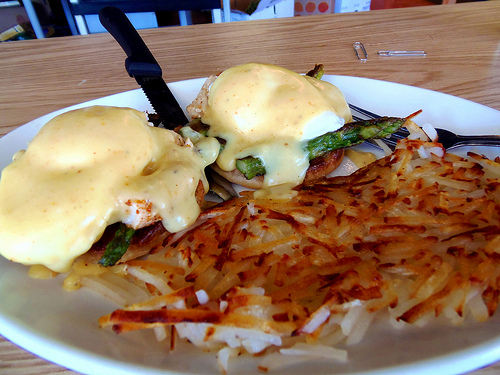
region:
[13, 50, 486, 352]
A serving of eggs and hash browns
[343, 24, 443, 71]
Two paperclips on the table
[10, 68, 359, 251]
A serving of eggs Benedict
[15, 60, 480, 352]
A large breakfast serving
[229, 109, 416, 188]
A piece of asparagus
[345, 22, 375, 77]
A paperclip on a table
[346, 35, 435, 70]
Two paperclips next to each other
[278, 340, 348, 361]
white colored hash brown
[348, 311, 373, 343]
white colored hash brown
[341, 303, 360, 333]
white colored hash brown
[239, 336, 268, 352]
white colored hash brown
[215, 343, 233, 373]
white colored hash brown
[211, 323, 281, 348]
white colored hash brown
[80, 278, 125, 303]
white colored hash brown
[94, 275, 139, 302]
white colored hash brown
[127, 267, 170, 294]
white colored hash brown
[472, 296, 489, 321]
white colored hash brown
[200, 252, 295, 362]
section of a food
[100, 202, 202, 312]
section of a food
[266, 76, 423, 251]
section of a food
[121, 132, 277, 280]
section of a food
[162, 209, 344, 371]
section of a food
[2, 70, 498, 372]
white plate with food on it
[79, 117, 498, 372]
hashbrowns on a plate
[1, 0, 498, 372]
wooden table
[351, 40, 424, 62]
two paperclips on a wooden table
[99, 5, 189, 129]
knife with a black handle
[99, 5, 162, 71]
black knife handle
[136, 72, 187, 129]
serrated blade of knife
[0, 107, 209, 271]
orange sauce on food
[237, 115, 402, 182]
green asperagus with sauce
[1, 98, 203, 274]
poached egg with hollandaise sauce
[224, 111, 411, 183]
spear of green asparagus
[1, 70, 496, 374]
white ceramic breakfast plate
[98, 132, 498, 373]
golden brown potato hashbrowns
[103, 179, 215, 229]
sprinkle of red paprika on egg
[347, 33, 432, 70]
two metal paperclips on table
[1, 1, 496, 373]
light brown wooden tabletop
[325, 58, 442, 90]
curved wood grain lines on table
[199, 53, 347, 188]
hollandaise sauce drizzled on eggs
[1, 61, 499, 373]
Plate full of delicious food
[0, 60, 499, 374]
Round white plate of food on table